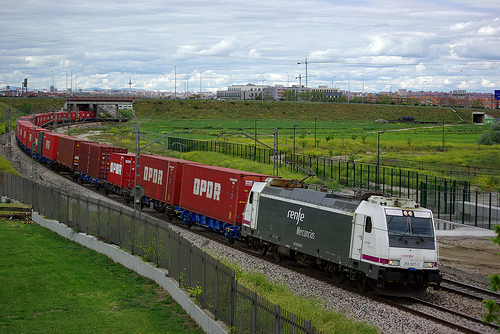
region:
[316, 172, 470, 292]
the front of a train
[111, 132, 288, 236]
a red train car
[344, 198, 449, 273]
the windshield on a train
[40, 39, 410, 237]
a very long train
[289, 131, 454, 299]
a train rolling on train tracks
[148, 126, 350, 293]
a train near train tracks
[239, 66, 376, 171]
a field near a train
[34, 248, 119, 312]
a grassy area near a train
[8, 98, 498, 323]
a train on rails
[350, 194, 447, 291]
front cabin of train is white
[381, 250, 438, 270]
headlights on train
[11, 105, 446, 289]
a freight train on the railroad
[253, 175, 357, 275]
car of train is green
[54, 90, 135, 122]
a bridge over railroad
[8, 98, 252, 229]
red cars of freight train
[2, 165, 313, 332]
a fence on side a train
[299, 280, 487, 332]
gravel on railroad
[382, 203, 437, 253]
wipes on windshield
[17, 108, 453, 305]
Train on the tracks.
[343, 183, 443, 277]
White front on the train.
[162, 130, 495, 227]
black fence beside the tracks.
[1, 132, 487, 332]
Gravel beside the tracks.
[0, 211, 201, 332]
Green grass covering the ground.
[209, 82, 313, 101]
Building in the background.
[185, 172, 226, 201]
white lettering on the train.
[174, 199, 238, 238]
Blue coloring on the bottom of the train.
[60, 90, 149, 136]
Bridge in the background.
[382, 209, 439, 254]
window in the front of the train.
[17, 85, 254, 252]
Red and white train cars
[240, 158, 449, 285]
Grey and white head car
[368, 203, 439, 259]
LArge black window for driver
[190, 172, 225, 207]
White logo on train car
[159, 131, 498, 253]
Black fence in the grass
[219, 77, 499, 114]
Buildings in the distance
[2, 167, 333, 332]
Silver chain link fence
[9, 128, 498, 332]
brown grey and white gravel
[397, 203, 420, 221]
Black and white number sign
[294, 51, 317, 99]
Silver light lamp posts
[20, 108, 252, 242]
cargo container is red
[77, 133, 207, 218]
cargo container is red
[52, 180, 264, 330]
the fence is gray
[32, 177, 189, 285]
the fence is gray